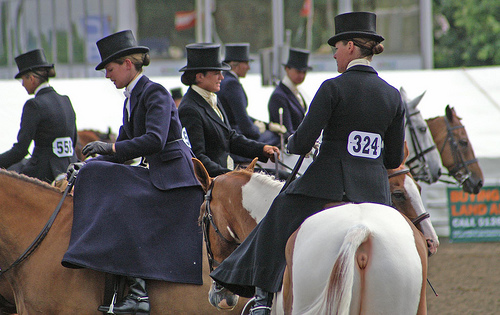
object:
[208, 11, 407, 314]
rider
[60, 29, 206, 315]
rider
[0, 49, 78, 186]
rider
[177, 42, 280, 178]
rider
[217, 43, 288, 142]
rider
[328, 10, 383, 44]
hat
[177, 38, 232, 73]
hat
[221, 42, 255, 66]
hat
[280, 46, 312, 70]
hat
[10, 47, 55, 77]
hat